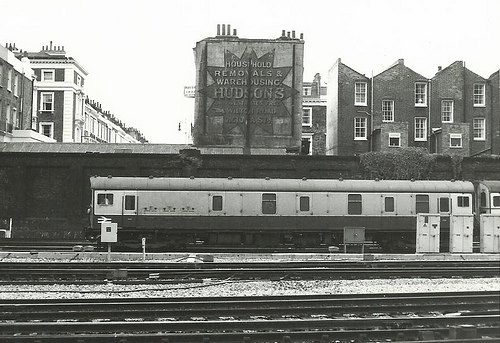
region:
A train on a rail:
[89, 176, 499, 243]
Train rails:
[0, 262, 498, 339]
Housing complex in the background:
[327, 58, 499, 151]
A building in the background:
[0, 39, 149, 141]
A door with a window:
[122, 192, 138, 229]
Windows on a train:
[209, 194, 431, 217]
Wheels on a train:
[100, 231, 415, 251]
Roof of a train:
[89, 177, 499, 194]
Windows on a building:
[40, 69, 52, 137]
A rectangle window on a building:
[40, 91, 52, 108]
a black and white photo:
[10, 40, 485, 340]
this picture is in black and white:
[37, 29, 292, 317]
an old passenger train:
[71, 156, 472, 246]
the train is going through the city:
[53, 56, 498, 257]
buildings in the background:
[12, 35, 497, 140]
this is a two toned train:
[70, 150, 485, 241]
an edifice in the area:
[10, 50, 138, 141]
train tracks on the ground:
[8, 251, 498, 329]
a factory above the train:
[201, 40, 297, 146]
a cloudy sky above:
[84, 4, 451, 36]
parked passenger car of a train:
[77, 172, 478, 255]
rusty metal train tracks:
[4, 255, 499, 342]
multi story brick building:
[370, 51, 427, 151]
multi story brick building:
[430, 58, 490, 156]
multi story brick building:
[329, 56, 370, 158]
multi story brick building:
[22, 37, 92, 145]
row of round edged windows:
[92, 183, 477, 216]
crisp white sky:
[2, 0, 498, 145]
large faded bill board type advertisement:
[189, 34, 307, 154]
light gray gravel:
[0, 270, 499, 300]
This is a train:
[74, 150, 494, 278]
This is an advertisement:
[182, 32, 319, 173]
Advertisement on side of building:
[192, 35, 298, 179]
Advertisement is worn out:
[198, 30, 314, 162]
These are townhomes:
[321, 60, 498, 167]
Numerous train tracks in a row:
[0, 238, 497, 340]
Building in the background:
[0, 38, 164, 155]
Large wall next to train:
[3, 137, 492, 261]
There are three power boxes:
[408, 210, 497, 264]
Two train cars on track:
[90, 155, 497, 258]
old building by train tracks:
[196, 24, 305, 150]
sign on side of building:
[207, 40, 302, 138]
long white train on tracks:
[89, 175, 468, 232]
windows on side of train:
[209, 188, 280, 213]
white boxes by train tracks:
[417, 210, 489, 250]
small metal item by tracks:
[341, 227, 367, 244]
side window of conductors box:
[105, 195, 113, 204]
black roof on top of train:
[162, 178, 301, 188]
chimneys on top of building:
[33, 43, 65, 55]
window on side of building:
[35, 88, 55, 109]